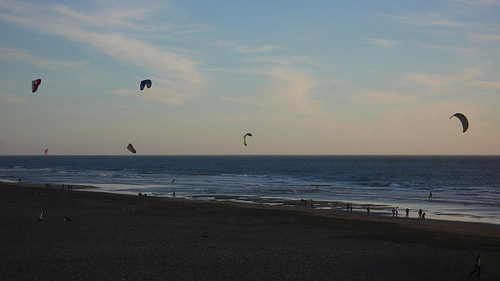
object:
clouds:
[346, 89, 488, 151]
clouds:
[74, 22, 199, 93]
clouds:
[9, 2, 165, 38]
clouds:
[51, 109, 212, 152]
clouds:
[391, 7, 499, 45]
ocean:
[1, 151, 499, 227]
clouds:
[181, 53, 361, 107]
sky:
[116, 19, 493, 146]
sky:
[296, 5, 423, 90]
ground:
[3, 189, 500, 235]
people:
[282, 186, 442, 226]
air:
[0, 0, 499, 156]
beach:
[2, 171, 500, 279]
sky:
[169, 27, 382, 92]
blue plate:
[168, 28, 228, 63]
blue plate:
[232, 47, 425, 115]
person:
[424, 187, 436, 202]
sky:
[124, 10, 388, 108]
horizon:
[16, 138, 476, 149]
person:
[366, 201, 371, 211]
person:
[350, 203, 352, 211]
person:
[344, 202, 350, 211]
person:
[404, 207, 412, 218]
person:
[389, 202, 395, 217]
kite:
[37, 145, 56, 162]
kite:
[30, 77, 42, 93]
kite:
[137, 75, 156, 92]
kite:
[239, 129, 253, 146]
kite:
[451, 112, 469, 136]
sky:
[16, 5, 140, 75]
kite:
[132, 72, 159, 93]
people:
[130, 187, 440, 226]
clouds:
[0, 0, 499, 154]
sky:
[2, 119, 494, 151]